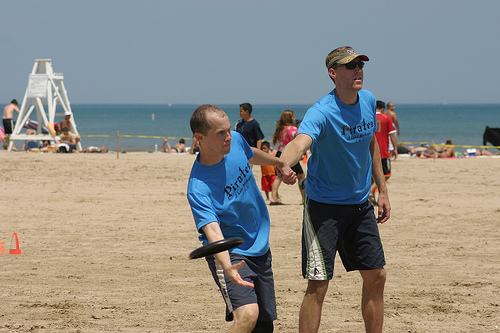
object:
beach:
[57, 200, 163, 293]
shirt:
[303, 95, 383, 206]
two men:
[180, 44, 402, 220]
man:
[162, 82, 283, 305]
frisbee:
[185, 230, 246, 262]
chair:
[13, 54, 84, 156]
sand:
[86, 158, 179, 315]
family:
[218, 79, 305, 200]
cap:
[326, 44, 370, 68]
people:
[397, 108, 460, 184]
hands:
[270, 153, 308, 191]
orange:
[6, 224, 30, 267]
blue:
[333, 144, 370, 193]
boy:
[258, 138, 274, 202]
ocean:
[103, 103, 135, 133]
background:
[22, 80, 494, 126]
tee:
[235, 115, 264, 138]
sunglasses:
[343, 58, 366, 69]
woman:
[281, 109, 296, 144]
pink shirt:
[273, 108, 305, 142]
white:
[30, 76, 48, 95]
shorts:
[296, 194, 429, 274]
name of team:
[224, 162, 261, 197]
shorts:
[257, 170, 277, 191]